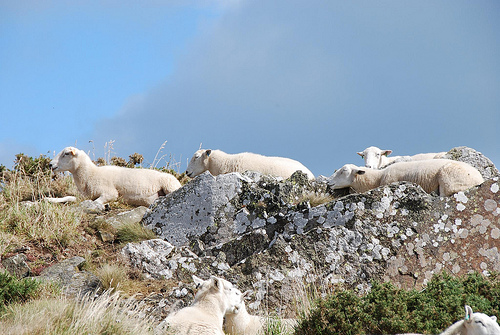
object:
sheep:
[438, 304, 500, 335]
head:
[185, 149, 211, 178]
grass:
[7, 202, 84, 243]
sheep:
[49, 146, 182, 210]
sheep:
[326, 159, 484, 197]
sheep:
[185, 149, 316, 181]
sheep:
[356, 146, 447, 170]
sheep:
[153, 274, 242, 335]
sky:
[0, 0, 500, 171]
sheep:
[223, 301, 310, 335]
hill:
[0, 146, 500, 335]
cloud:
[0, 0, 500, 177]